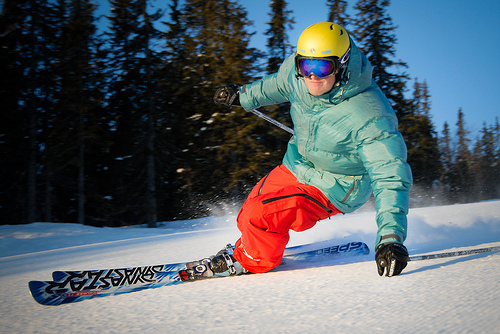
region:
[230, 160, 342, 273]
skier wearing red pants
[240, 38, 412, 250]
skier wearing light blue jacket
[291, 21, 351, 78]
skier wearing yellow helmet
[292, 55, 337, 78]
reflective goggles under helmet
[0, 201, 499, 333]
left hand touching snow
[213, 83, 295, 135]
right hand holding ski pole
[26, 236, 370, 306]
long skis are parallel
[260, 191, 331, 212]
pants zipper is black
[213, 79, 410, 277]
skier wears black gloves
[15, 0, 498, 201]
winter sky is blue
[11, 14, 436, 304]
skier going sideways in the snow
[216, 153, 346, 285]
bright orange snowpants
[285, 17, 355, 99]
bright yellow helmets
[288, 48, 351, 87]
goggles with bright blue eye cover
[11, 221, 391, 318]
blue skis with black letters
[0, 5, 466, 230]
long line of pine trees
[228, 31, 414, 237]
skier wearing a light blue jacket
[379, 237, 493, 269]
ski pole against the ground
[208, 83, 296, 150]
gloved hand holding a ski pole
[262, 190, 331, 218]
black stripe on orange pants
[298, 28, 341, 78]
yellow ski helmet with blue goggles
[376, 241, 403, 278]
black ski glove touching the snow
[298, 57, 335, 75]
reflective ski goggles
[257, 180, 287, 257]
orange ski pants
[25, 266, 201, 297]
pair of skis on the snow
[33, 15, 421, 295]
person in a puffy coat skiing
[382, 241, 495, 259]
skier's pole near the ground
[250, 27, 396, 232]
skier wearing a yellow helmet and orange pants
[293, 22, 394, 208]
skier wearing goggles and a puffy coat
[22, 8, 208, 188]
pine trees on the snowy mountain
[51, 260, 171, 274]
the right ski in snow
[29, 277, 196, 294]
left ski in snow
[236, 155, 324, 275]
the pants are orange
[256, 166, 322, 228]
black stripes on pants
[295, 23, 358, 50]
the helmet is yellow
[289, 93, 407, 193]
the jacket is green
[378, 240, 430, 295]
the gloves are black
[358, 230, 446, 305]
the hand is touching snow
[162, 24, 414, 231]
the trees behind skier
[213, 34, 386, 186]
skier holding the pole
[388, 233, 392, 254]
part of a glove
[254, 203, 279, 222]
part of a track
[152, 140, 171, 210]
stem of a tree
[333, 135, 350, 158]
part of a jacket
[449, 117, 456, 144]
part of the sky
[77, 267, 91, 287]
part of a board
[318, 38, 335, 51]
part of an helmet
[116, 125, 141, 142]
part of a forest